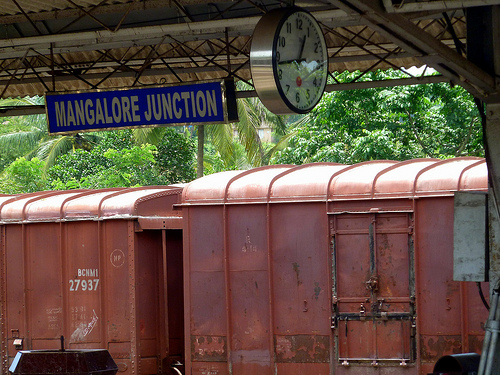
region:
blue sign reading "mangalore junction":
[40, 79, 235, 129]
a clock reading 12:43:
[262, 8, 334, 113]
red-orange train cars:
[2, 154, 497, 368]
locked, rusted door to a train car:
[318, 207, 424, 372]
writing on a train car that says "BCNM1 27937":
[60, 253, 116, 305]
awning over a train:
[0, 1, 493, 95]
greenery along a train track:
[0, 114, 490, 186]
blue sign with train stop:
[40, 81, 238, 123]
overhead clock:
[255, 8, 332, 111]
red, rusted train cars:
[11, 179, 494, 367]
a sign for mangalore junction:
[38, 59, 242, 141]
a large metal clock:
[237, 10, 337, 131]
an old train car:
[173, 155, 497, 374]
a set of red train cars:
[7, 142, 499, 372]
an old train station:
[8, 5, 495, 371]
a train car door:
[281, 155, 452, 373]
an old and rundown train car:
[3, 147, 498, 372]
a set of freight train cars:
[6, 133, 493, 373]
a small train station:
[8, 5, 492, 373]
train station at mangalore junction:
[8, 2, 492, 372]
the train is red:
[0, 158, 473, 358]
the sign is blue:
[37, 80, 236, 146]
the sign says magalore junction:
[46, 79, 278, 142]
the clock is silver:
[247, 8, 357, 135]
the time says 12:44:
[254, 10, 369, 132]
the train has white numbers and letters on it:
[57, 250, 167, 328]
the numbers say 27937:
[42, 257, 158, 308]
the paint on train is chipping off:
[238, 227, 493, 347]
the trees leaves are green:
[12, 111, 497, 164]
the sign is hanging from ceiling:
[41, 3, 238, 133]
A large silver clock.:
[245, 9, 329, 117]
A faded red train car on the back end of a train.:
[1, 177, 186, 374]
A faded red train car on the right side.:
[184, 154, 496, 374]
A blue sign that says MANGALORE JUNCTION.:
[39, 78, 236, 132]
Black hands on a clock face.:
[276, 31, 310, 67]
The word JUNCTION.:
[140, 88, 220, 123]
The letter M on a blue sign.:
[51, 99, 67, 128]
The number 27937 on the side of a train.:
[66, 279, 100, 292]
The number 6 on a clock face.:
[292, 88, 301, 106]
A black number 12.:
[294, 17, 304, 31]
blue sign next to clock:
[38, 63, 235, 150]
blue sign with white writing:
[29, 83, 221, 158]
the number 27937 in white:
[63, 278, 107, 302]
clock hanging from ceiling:
[257, 8, 341, 110]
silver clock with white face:
[246, 9, 347, 124]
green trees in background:
[362, 108, 426, 153]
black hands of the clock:
[276, 35, 320, 75]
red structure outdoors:
[10, 184, 146, 306]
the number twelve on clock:
[289, 8, 312, 38]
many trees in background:
[8, 101, 373, 195]